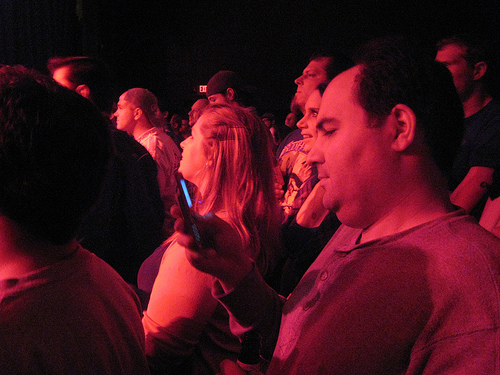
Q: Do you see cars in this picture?
A: No, there are no cars.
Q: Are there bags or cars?
A: No, there are no cars or bags.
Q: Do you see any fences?
A: No, there are no fences.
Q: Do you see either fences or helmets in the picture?
A: No, there are no fences or helmets.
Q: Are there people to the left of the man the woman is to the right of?
A: Yes, there is a person to the left of the man.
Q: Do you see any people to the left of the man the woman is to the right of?
A: Yes, there is a person to the left of the man.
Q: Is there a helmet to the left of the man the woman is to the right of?
A: No, there is a person to the left of the man.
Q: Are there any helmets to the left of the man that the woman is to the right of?
A: No, there is a person to the left of the man.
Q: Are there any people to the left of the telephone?
A: Yes, there is a person to the left of the telephone.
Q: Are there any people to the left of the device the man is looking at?
A: Yes, there is a person to the left of the telephone.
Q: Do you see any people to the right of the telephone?
A: No, the person is to the left of the telephone.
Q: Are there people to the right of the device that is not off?
A: No, the person is to the left of the telephone.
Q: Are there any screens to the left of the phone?
A: No, there is a person to the left of the phone.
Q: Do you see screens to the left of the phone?
A: No, there is a person to the left of the phone.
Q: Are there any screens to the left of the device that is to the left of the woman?
A: No, there is a person to the left of the phone.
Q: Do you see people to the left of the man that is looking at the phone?
A: Yes, there is a person to the left of the man.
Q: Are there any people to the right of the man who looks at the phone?
A: No, the person is to the left of the man.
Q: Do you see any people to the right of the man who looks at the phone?
A: No, the person is to the left of the man.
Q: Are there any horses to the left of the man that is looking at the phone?
A: No, there is a person to the left of the man.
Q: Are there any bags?
A: No, there are no bags.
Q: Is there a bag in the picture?
A: No, there are no bags.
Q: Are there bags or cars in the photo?
A: No, there are no bags or cars.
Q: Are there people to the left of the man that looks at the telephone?
A: Yes, there is a person to the left of the man.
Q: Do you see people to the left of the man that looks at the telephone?
A: Yes, there is a person to the left of the man.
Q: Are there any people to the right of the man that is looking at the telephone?
A: No, the person is to the left of the man.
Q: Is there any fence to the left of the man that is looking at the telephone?
A: No, there is a person to the left of the man.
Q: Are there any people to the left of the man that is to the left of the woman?
A: Yes, there is a person to the left of the man.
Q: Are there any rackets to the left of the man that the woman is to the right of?
A: No, there is a person to the left of the man.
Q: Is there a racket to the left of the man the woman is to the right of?
A: No, there is a person to the left of the man.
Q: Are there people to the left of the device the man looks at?
A: Yes, there is a person to the left of the telephone.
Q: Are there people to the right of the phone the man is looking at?
A: No, the person is to the left of the phone.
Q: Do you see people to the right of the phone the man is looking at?
A: No, the person is to the left of the phone.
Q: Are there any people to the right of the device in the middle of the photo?
A: No, the person is to the left of the phone.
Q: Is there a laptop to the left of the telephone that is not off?
A: No, there is a person to the left of the phone.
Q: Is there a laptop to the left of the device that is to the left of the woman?
A: No, there is a person to the left of the phone.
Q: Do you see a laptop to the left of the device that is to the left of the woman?
A: No, there is a person to the left of the phone.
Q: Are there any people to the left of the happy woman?
A: Yes, there is a person to the left of the woman.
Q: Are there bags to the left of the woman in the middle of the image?
A: No, there is a person to the left of the woman.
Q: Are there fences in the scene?
A: No, there are no fences.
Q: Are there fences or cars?
A: No, there are no fences or cars.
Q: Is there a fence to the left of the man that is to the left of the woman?
A: No, there is a person to the left of the man.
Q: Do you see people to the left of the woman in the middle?
A: Yes, there is a person to the left of the woman.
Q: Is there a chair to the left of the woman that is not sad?
A: No, there is a person to the left of the woman.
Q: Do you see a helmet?
A: No, there are no helmets.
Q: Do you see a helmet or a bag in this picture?
A: No, there are no helmets or bags.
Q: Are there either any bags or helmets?
A: No, there are no helmets or bags.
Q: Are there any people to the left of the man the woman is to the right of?
A: Yes, there is a person to the left of the man.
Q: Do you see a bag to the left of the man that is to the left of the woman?
A: No, there is a person to the left of the man.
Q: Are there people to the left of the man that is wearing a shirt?
A: Yes, there is a person to the left of the man.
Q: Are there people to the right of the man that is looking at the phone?
A: No, the person is to the left of the man.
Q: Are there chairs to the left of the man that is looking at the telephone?
A: No, there is a person to the left of the man.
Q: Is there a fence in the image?
A: No, there are no fences.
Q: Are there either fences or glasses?
A: No, there are no fences or glasses.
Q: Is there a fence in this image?
A: No, there are no fences.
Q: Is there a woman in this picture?
A: Yes, there is a woman.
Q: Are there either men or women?
A: Yes, there is a woman.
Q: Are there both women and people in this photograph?
A: Yes, there are both a woman and people.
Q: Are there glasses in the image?
A: No, there are no glasses.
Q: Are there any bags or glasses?
A: No, there are no glasses or bags.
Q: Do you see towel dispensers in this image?
A: No, there are no towel dispensers.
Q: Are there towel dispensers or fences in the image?
A: No, there are no towel dispensers or fences.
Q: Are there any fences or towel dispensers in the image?
A: No, there are no towel dispensers or fences.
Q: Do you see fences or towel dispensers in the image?
A: No, there are no towel dispensers or fences.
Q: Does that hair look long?
A: Yes, the hair is long.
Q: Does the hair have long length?
A: Yes, the hair is long.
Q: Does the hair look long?
A: Yes, the hair is long.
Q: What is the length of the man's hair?
A: The hair is long.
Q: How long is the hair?
A: The hair is long.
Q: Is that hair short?
A: No, the hair is long.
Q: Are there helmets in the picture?
A: No, there are no helmets.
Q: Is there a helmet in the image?
A: No, there are no helmets.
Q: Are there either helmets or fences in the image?
A: No, there are no helmets or fences.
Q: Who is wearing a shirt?
A: The man is wearing a shirt.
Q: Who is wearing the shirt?
A: The man is wearing a shirt.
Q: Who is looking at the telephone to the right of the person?
A: The man is looking at the phone.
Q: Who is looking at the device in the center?
A: The man is looking at the phone.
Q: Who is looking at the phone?
A: The man is looking at the phone.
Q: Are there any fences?
A: No, there are no fences.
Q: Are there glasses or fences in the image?
A: No, there are no fences or glasses.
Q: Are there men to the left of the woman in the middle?
A: Yes, there is a man to the left of the woman.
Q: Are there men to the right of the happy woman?
A: No, the man is to the left of the woman.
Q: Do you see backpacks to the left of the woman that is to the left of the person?
A: No, there is a man to the left of the woman.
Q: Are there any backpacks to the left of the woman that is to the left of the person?
A: No, there is a man to the left of the woman.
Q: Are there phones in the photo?
A: Yes, there is a phone.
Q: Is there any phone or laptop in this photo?
A: Yes, there is a phone.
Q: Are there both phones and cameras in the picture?
A: No, there is a phone but no cameras.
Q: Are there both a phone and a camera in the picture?
A: No, there is a phone but no cameras.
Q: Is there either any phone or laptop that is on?
A: Yes, the phone is on.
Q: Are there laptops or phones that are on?
A: Yes, the phone is on.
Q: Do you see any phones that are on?
A: Yes, there is a phone that is on.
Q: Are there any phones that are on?
A: Yes, there is a phone that is on.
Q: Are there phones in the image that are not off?
A: Yes, there is a phone that is on.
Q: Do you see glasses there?
A: No, there are no glasses.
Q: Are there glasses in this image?
A: No, there are no glasses.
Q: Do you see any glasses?
A: No, there are no glasses.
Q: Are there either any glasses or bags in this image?
A: No, there are no glasses or bags.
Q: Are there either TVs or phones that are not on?
A: No, there is a phone but it is on.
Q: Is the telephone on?
A: Yes, the telephone is on.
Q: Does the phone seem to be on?
A: Yes, the phone is on.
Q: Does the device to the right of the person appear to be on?
A: Yes, the phone is on.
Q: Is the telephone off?
A: No, the telephone is on.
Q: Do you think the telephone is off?
A: No, the telephone is on.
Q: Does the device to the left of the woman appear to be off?
A: No, the telephone is on.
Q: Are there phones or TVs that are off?
A: No, there is a phone but it is on.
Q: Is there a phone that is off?
A: No, there is a phone but it is on.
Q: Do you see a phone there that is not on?
A: No, there is a phone but it is on.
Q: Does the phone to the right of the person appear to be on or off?
A: The phone is on.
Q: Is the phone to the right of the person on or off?
A: The phone is on.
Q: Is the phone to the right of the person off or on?
A: The phone is on.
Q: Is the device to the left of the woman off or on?
A: The phone is on.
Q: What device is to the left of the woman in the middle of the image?
A: The device is a phone.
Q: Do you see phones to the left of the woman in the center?
A: Yes, there is a phone to the left of the woman.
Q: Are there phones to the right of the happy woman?
A: No, the phone is to the left of the woman.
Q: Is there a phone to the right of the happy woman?
A: No, the phone is to the left of the woman.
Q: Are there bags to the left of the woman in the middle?
A: No, there is a phone to the left of the woman.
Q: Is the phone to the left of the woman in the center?
A: Yes, the phone is to the left of the woman.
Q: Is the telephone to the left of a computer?
A: No, the telephone is to the left of the woman.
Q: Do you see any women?
A: Yes, there is a woman.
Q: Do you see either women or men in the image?
A: Yes, there is a woman.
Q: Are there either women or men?
A: Yes, there is a woman.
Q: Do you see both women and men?
A: Yes, there are both a woman and a man.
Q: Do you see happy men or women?
A: Yes, there is a happy woman.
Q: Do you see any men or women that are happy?
A: Yes, the woman is happy.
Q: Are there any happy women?
A: Yes, there is a happy woman.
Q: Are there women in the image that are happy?
A: Yes, there is a woman that is happy.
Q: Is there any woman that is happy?
A: Yes, there is a woman that is happy.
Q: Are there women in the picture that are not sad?
A: Yes, there is a happy woman.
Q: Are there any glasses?
A: No, there are no glasses.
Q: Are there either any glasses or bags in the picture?
A: No, there are no glasses or bags.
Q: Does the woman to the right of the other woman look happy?
A: Yes, the woman is happy.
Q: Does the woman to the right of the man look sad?
A: No, the woman is happy.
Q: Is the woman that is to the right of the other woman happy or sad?
A: The woman is happy.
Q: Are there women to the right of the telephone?
A: Yes, there is a woman to the right of the telephone.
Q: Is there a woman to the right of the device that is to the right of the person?
A: Yes, there is a woman to the right of the telephone.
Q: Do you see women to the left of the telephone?
A: No, the woman is to the right of the telephone.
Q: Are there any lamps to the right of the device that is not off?
A: No, there is a woman to the right of the phone.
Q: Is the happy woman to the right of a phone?
A: Yes, the woman is to the right of a phone.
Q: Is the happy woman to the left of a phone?
A: No, the woman is to the right of a phone.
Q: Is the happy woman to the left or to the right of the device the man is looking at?
A: The woman is to the right of the telephone.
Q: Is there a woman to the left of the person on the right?
A: Yes, there is a woman to the left of the person.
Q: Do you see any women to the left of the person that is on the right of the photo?
A: Yes, there is a woman to the left of the person.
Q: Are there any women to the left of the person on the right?
A: Yes, there is a woman to the left of the person.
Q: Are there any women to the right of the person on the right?
A: No, the woman is to the left of the person.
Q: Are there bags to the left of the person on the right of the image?
A: No, there is a woman to the left of the person.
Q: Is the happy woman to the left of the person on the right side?
A: Yes, the woman is to the left of the person.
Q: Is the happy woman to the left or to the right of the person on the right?
A: The woman is to the left of the person.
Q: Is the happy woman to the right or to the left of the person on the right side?
A: The woman is to the left of the person.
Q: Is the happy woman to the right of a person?
A: Yes, the woman is to the right of a person.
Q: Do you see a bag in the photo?
A: No, there are no bags.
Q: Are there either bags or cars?
A: No, there are no bags or cars.